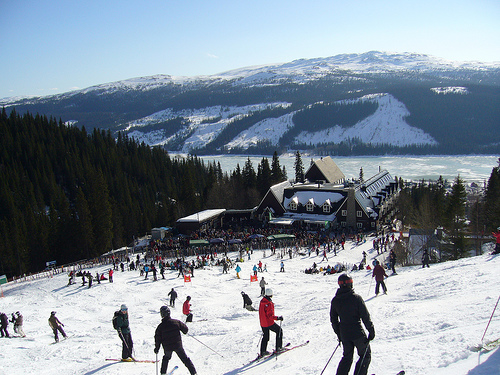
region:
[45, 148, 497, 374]
a ski resort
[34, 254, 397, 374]
people skiing in the snow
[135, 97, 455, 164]
Downhill ski slopes on a mountain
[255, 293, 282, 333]
a person wearing a red jacket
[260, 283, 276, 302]
a person wearing a white hat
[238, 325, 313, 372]
a person on downhill skiis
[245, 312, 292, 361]
a person holding ski poles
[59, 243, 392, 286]
Lots of people in the snow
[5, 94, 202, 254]
Trees on the hillside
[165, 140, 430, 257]
A building in the distance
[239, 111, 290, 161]
a patch of snow on mountain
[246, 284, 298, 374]
a skier wearing a red jacket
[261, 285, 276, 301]
a white knit cap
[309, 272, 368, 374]
a skier wearing a black jacket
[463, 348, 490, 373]
a shadow on the snow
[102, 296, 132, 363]
a skier with a backpack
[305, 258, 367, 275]
people sitting in the snow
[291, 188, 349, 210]
white snow on a roof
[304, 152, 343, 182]
a peaked rooftop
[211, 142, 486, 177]
a frozen lake behind the building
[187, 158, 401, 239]
ski lodge in mountains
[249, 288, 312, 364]
wearing red ski outfit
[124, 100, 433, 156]
snow covered mountain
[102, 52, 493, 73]
large snow covered mountain in distance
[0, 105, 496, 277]
trees surrounding ski lodge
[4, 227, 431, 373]
lots of people surrounding ski lodge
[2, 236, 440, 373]
people taking advantage of the snow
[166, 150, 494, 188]
looks like a large river or mass of water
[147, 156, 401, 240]
large building surrounded by trees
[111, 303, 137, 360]
wearing ski hat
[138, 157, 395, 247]
a large ski lodge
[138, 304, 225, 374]
skier extends poles out to either side of him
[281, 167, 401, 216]
roof has many dormers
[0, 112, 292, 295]
tall pines frame the slope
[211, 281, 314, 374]
skier wearing red coat with white hat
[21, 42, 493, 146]
distant slopes across the water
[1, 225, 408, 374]
large crowd gathered for sking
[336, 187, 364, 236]
a chimeny on the ski lodge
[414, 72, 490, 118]
a smaller clearing on top of far mountain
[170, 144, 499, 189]
a frozen lake down below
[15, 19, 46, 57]
white clouds in blue sky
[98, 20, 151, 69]
white clouds in blue sky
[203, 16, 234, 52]
white clouds in blue sky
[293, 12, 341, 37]
white clouds in blue sky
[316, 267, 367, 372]
skier standing in white snow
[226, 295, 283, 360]
skier standing in white snow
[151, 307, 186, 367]
skier standing in white snow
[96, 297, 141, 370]
skier standing in white snow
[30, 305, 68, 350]
skier standing in white snow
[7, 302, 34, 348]
skier standing in white snow